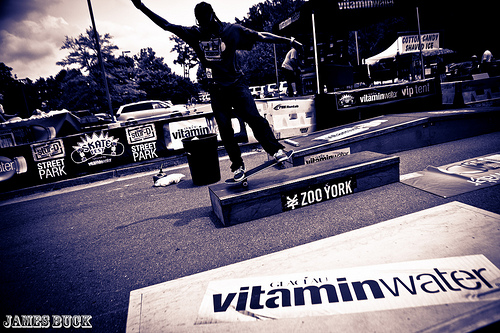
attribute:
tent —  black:
[301, 0, 401, 88]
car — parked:
[109, 87, 197, 129]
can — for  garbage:
[170, 130, 212, 182]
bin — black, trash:
[181, 131, 221, 186]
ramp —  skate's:
[206, 133, 406, 231]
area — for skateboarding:
[5, 3, 496, 330]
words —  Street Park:
[36, 156, 66, 177]